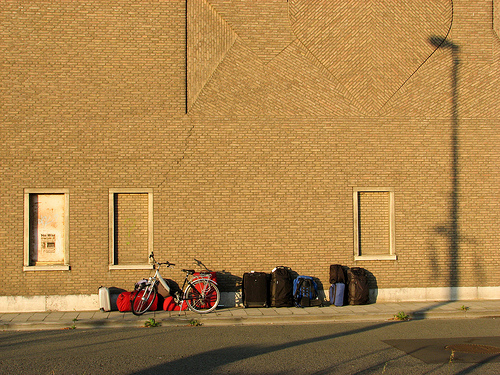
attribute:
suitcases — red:
[122, 271, 211, 312]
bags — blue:
[296, 262, 342, 314]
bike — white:
[125, 254, 228, 313]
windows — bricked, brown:
[106, 182, 398, 259]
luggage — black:
[244, 259, 288, 309]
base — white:
[0, 285, 103, 317]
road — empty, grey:
[14, 308, 488, 363]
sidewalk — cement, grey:
[248, 288, 477, 322]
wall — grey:
[40, 34, 497, 179]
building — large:
[23, 14, 497, 310]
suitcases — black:
[246, 270, 270, 307]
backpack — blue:
[297, 279, 319, 303]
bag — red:
[109, 286, 157, 314]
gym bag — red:
[159, 297, 188, 317]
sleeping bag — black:
[274, 262, 287, 310]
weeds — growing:
[134, 309, 418, 345]